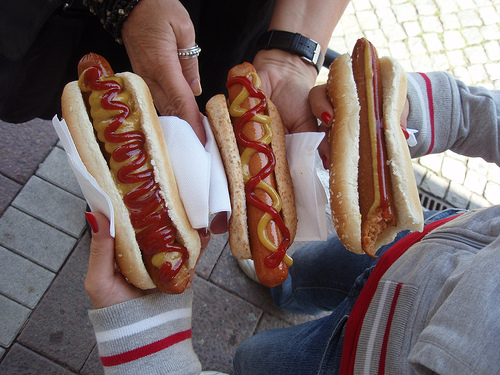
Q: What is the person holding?
A: Hot Dog.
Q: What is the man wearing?
A: Clothes.